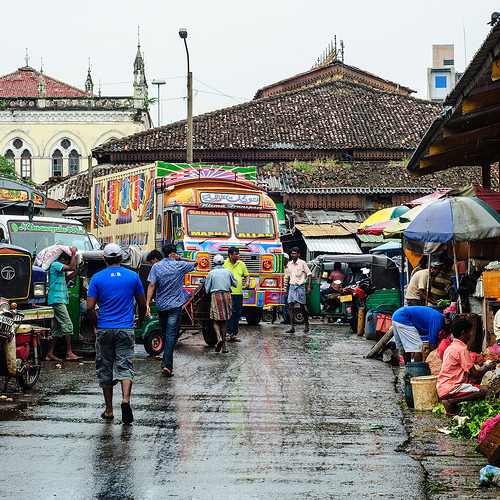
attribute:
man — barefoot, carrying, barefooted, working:
[71, 227, 147, 446]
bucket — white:
[396, 348, 451, 418]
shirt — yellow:
[218, 256, 258, 304]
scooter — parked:
[0, 294, 67, 389]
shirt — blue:
[82, 251, 169, 338]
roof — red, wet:
[0, 61, 129, 111]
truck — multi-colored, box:
[64, 163, 305, 273]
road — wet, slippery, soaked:
[156, 308, 356, 494]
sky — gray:
[260, 17, 307, 67]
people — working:
[43, 155, 320, 462]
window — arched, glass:
[38, 154, 90, 179]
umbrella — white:
[368, 144, 485, 162]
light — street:
[149, 26, 225, 154]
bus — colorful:
[86, 134, 319, 327]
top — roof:
[0, 60, 80, 116]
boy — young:
[411, 302, 487, 398]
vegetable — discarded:
[419, 377, 496, 456]